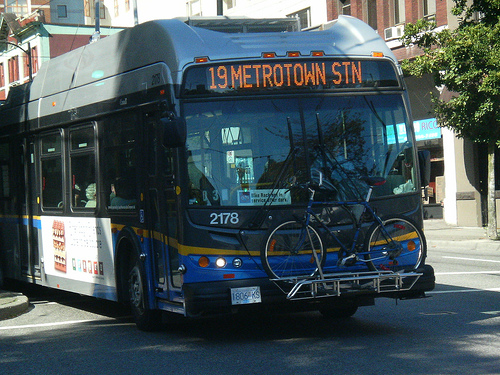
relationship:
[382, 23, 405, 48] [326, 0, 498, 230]
ac on building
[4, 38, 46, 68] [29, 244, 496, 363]
street light on road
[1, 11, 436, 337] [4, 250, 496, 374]
bus on road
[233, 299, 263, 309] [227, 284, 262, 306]
edge of plate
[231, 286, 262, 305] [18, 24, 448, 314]
numberplate of bus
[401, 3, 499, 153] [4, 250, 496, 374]
tree in road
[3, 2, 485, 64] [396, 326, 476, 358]
buildings on road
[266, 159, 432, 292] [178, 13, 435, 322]
bike on bus front